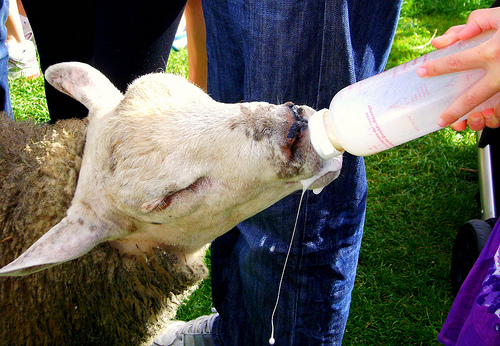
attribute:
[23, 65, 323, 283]
sheep — white, eating, dirty, brown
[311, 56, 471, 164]
bottle — white, plastic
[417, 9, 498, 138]
person — white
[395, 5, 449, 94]
grass — green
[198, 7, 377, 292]
jeans — blue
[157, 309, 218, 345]
shoe — white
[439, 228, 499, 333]
cloth — purple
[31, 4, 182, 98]
pants — black